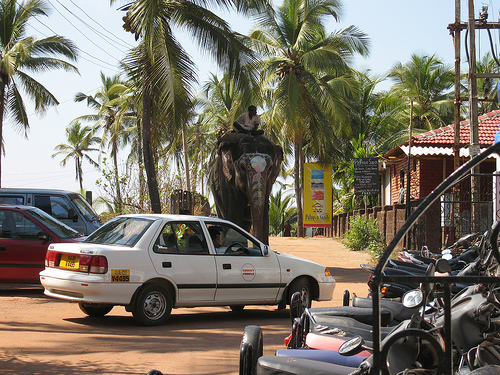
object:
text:
[65, 255, 76, 267]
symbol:
[239, 261, 258, 281]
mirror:
[399, 286, 422, 309]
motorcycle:
[359, 261, 500, 287]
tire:
[133, 281, 178, 328]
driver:
[204, 225, 235, 252]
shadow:
[145, 320, 235, 370]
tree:
[369, 241, 383, 263]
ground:
[0, 284, 311, 375]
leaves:
[311, 77, 353, 113]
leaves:
[223, 55, 245, 57]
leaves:
[324, 112, 339, 127]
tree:
[236, 0, 368, 163]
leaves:
[314, 113, 329, 117]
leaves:
[333, 56, 344, 73]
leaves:
[119, 81, 139, 86]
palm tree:
[50, 124, 105, 194]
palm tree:
[74, 71, 139, 215]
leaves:
[96, 137, 103, 147]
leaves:
[57, 148, 67, 158]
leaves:
[423, 116, 438, 127]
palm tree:
[327, 69, 392, 164]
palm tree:
[371, 51, 471, 149]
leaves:
[411, 64, 446, 87]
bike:
[278, 291, 500, 352]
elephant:
[205, 123, 285, 247]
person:
[208, 225, 221, 250]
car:
[37, 211, 334, 326]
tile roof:
[412, 110, 499, 141]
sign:
[305, 159, 333, 223]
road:
[276, 226, 397, 309]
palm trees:
[2, 0, 79, 137]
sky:
[3, 0, 498, 192]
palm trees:
[115, 0, 245, 215]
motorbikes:
[341, 289, 498, 321]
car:
[0, 204, 85, 287]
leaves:
[71, 130, 86, 138]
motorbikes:
[288, 292, 500, 339]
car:
[0, 188, 106, 237]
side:
[107, 222, 282, 307]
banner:
[300, 161, 333, 227]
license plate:
[57, 255, 81, 269]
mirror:
[338, 336, 365, 357]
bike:
[236, 287, 500, 375]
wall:
[337, 134, 440, 251]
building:
[332, 106, 499, 271]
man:
[230, 105, 267, 134]